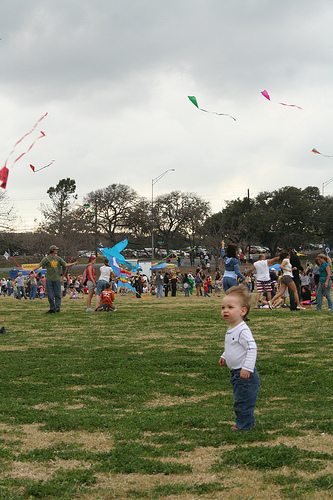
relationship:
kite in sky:
[259, 88, 283, 107] [173, 40, 211, 67]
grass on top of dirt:
[138, 361, 187, 383] [157, 396, 177, 404]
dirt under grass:
[157, 396, 177, 404] [138, 361, 187, 383]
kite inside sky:
[259, 88, 283, 107] [173, 40, 211, 67]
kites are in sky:
[185, 84, 286, 122] [173, 40, 211, 67]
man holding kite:
[77, 251, 105, 318] [259, 88, 283, 107]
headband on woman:
[88, 257, 93, 260] [77, 264, 101, 315]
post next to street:
[144, 184, 160, 209] [54, 248, 80, 259]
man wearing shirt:
[77, 251, 105, 318] [97, 292, 111, 304]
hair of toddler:
[230, 286, 237, 297] [205, 280, 258, 416]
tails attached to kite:
[286, 101, 304, 112] [259, 88, 283, 107]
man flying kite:
[77, 251, 105, 318] [259, 88, 283, 107]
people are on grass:
[145, 247, 237, 316] [138, 361, 187, 383]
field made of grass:
[0, 350, 97, 427] [138, 361, 187, 383]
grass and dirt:
[138, 361, 187, 383] [20, 424, 319, 495]